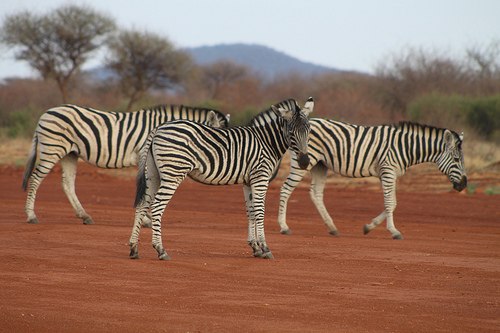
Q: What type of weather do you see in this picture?
A: It is overcast.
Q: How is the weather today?
A: It is overcast.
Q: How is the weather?
A: It is overcast.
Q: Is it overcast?
A: Yes, it is overcast.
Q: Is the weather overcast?
A: Yes, it is overcast.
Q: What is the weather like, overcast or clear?
A: It is overcast.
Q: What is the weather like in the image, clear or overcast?
A: It is overcast.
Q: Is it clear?
A: No, it is overcast.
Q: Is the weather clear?
A: No, it is overcast.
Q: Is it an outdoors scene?
A: Yes, it is outdoors.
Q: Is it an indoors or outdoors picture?
A: It is outdoors.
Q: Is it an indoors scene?
A: No, it is outdoors.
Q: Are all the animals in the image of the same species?
A: Yes, all the animals are zebras.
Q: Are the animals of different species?
A: No, all the animals are zebras.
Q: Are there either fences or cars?
A: No, there are no fences or cars.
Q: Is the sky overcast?
A: Yes, the sky is overcast.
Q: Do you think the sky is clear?
A: No, the sky is overcast.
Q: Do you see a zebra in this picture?
A: Yes, there is a zebra.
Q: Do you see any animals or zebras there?
A: Yes, there is a zebra.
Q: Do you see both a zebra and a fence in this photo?
A: No, there is a zebra but no fences.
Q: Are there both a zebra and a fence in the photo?
A: No, there is a zebra but no fences.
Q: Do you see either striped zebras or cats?
A: Yes, there is a striped zebra.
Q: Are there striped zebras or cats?
A: Yes, there is a striped zebra.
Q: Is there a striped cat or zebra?
A: Yes, there is a striped zebra.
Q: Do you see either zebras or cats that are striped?
A: Yes, the zebra is striped.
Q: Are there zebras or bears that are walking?
A: Yes, the zebra is walking.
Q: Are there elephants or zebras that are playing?
A: Yes, the zebra is playing.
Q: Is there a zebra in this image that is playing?
A: Yes, there is a zebra that is playing.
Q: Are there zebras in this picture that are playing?
A: Yes, there is a zebra that is playing.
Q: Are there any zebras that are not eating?
A: Yes, there is a zebra that is playing.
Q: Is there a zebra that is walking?
A: Yes, there is a zebra that is walking.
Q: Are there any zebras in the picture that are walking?
A: Yes, there is a zebra that is walking.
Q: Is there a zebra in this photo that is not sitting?
A: Yes, there is a zebra that is walking.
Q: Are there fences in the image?
A: No, there are no fences.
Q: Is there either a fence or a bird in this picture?
A: No, there are no fences or birds.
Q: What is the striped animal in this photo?
A: The animal is a zebra.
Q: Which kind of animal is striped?
A: The animal is a zebra.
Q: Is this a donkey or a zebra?
A: This is a zebra.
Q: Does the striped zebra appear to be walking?
A: Yes, the zebra is walking.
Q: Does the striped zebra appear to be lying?
A: No, the zebra is walking.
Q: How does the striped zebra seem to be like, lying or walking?
A: The zebra is walking.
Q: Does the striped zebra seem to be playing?
A: Yes, the zebra is playing.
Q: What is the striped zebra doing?
A: The zebra is playing.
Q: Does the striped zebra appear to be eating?
A: No, the zebra is playing.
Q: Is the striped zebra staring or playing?
A: The zebra is playing.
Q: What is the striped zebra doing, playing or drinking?
A: The zebra is playing.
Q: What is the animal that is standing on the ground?
A: The animal is a zebra.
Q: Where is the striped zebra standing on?
A: The zebra is standing on the ground.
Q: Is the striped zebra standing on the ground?
A: Yes, the zebra is standing on the ground.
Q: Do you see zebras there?
A: Yes, there is a zebra.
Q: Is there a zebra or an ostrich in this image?
A: Yes, there is a zebra.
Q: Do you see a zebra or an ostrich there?
A: Yes, there is a zebra.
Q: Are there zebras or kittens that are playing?
A: Yes, the zebra is playing.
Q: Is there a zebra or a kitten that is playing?
A: Yes, the zebra is playing.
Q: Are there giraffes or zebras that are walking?
A: Yes, the zebra is walking.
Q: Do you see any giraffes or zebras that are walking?
A: Yes, the zebra is walking.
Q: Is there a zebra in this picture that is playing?
A: Yes, there is a zebra that is playing.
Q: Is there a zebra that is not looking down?
A: Yes, there is a zebra that is playing.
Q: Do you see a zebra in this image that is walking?
A: Yes, there is a zebra that is walking.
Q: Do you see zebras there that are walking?
A: Yes, there is a zebra that is walking.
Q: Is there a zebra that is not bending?
A: Yes, there is a zebra that is walking.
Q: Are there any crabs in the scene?
A: No, there are no crabs.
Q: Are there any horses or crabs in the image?
A: No, there are no crabs or horses.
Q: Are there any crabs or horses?
A: No, there are no crabs or horses.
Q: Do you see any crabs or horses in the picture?
A: No, there are no crabs or horses.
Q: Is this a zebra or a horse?
A: This is a zebra.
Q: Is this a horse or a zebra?
A: This is a zebra.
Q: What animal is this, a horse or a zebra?
A: This is a zebra.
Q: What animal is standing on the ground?
A: The zebra is standing on the ground.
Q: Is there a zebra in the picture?
A: Yes, there is a zebra.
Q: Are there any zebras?
A: Yes, there is a zebra.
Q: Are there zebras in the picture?
A: Yes, there is a zebra.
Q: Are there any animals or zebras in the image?
A: Yes, there is a zebra.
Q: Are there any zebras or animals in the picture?
A: Yes, there is a zebra.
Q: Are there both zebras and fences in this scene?
A: No, there is a zebra but no fences.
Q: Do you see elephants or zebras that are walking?
A: Yes, the zebra is walking.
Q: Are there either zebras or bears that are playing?
A: Yes, the zebra is playing.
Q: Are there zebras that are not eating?
A: Yes, there is a zebra that is playing.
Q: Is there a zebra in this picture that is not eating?
A: Yes, there is a zebra that is playing.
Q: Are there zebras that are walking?
A: Yes, there is a zebra that is walking.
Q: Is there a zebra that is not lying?
A: Yes, there is a zebra that is walking.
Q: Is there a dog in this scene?
A: No, there are no dogs.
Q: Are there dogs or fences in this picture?
A: No, there are no dogs or fences.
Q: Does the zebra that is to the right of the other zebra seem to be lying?
A: No, the zebra is walking.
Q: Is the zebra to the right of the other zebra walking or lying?
A: The zebra is walking.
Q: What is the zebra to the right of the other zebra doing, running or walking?
A: The zebra is walking.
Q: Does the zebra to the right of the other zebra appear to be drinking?
A: No, the zebra is playing.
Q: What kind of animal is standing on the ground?
A: The animal is a zebra.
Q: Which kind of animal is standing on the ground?
A: The animal is a zebra.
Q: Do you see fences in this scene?
A: No, there are no fences.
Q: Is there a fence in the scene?
A: No, there are no fences.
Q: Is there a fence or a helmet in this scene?
A: No, there are no fences or helmets.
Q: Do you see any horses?
A: No, there are no horses.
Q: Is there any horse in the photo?
A: No, there are no horses.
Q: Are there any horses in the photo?
A: No, there are no horses.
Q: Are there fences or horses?
A: No, there are no horses or fences.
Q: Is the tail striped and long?
A: Yes, the tail is striped and long.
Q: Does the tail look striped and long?
A: Yes, the tail is striped and long.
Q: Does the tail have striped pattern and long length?
A: Yes, the tail is striped and long.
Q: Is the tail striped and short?
A: No, the tail is striped but long.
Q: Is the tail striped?
A: Yes, the tail is striped.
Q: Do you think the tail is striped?
A: Yes, the tail is striped.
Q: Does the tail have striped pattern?
A: Yes, the tail is striped.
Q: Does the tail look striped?
A: Yes, the tail is striped.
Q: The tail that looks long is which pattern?
A: The tail is striped.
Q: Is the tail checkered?
A: No, the tail is striped.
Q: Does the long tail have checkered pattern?
A: No, the tail is striped.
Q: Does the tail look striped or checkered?
A: The tail is striped.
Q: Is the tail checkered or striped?
A: The tail is striped.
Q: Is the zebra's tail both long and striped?
A: Yes, the tail is long and striped.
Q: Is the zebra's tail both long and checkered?
A: No, the tail is long but striped.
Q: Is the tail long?
A: Yes, the tail is long.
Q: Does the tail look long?
A: Yes, the tail is long.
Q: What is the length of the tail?
A: The tail is long.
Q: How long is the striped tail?
A: The tail is long.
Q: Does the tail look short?
A: No, the tail is long.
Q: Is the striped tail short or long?
A: The tail is long.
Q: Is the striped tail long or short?
A: The tail is long.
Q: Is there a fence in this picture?
A: No, there are no fences.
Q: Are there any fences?
A: No, there are no fences.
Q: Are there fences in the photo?
A: No, there are no fences.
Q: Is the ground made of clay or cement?
A: The ground is made of clay.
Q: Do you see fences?
A: No, there are no fences.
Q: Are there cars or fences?
A: No, there are no fences or cars.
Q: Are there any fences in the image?
A: No, there are no fences.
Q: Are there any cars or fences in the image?
A: No, there are no fences or cars.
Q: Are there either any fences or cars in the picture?
A: No, there are no fences or cars.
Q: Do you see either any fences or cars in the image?
A: No, there are no fences or cars.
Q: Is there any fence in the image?
A: No, there are no fences.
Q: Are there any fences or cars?
A: No, there are no fences or cars.